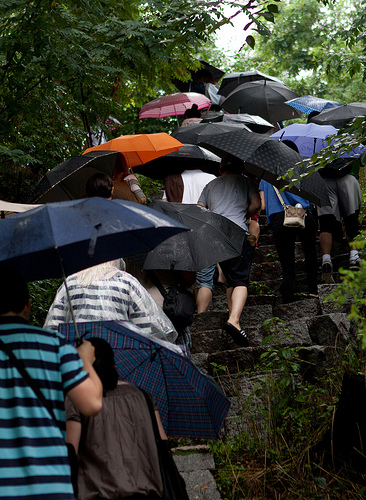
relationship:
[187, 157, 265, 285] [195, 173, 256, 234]
man wearing shirt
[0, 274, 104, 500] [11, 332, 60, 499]
man wearing shirt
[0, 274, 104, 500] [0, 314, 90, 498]
man wearing shirt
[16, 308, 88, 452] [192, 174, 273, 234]
man wearing shirt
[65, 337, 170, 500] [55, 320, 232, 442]
people holding umbrella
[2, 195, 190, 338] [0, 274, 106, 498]
umbrella held by person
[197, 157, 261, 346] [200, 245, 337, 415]
man walking up stairs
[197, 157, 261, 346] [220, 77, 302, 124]
man holding umbrella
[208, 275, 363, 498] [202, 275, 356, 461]
grass next to stairs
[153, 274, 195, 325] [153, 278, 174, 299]
bag on shoulder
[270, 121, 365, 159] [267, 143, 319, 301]
blue umbrella held by person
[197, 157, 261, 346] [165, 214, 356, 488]
man walking up stairs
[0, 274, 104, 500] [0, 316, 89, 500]
man wearing a black shirt